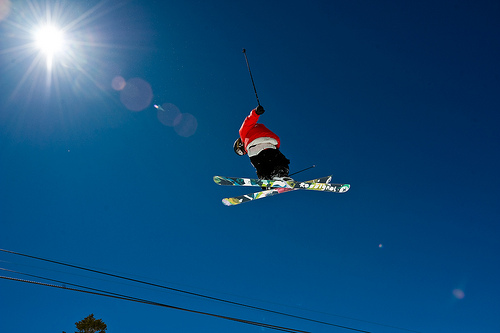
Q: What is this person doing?
A: Skiing.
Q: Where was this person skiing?
A: At the ski resort.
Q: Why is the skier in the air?
A: They are performing a jump.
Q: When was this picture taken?
A: Wintertime.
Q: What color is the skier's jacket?
A: Red.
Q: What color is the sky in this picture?
A: Blue.